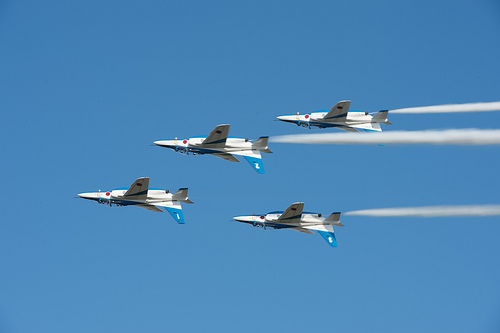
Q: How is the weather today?
A: It is clear.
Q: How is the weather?
A: It is clear.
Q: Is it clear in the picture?
A: Yes, it is clear.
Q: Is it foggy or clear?
A: It is clear.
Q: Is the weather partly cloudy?
A: No, it is clear.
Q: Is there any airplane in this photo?
A: Yes, there is an airplane.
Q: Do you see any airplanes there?
A: Yes, there is an airplane.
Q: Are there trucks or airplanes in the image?
A: Yes, there is an airplane.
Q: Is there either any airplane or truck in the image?
A: Yes, there is an airplane.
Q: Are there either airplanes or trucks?
A: Yes, there is an airplane.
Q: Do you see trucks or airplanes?
A: Yes, there is an airplane.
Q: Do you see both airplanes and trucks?
A: No, there is an airplane but no trucks.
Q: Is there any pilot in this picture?
A: No, there are no pilots.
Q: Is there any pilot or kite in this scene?
A: No, there are no pilots or kites.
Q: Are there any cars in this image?
A: No, there are no cars.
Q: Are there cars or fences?
A: No, there are no cars or fences.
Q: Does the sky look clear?
A: Yes, the sky is clear.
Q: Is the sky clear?
A: Yes, the sky is clear.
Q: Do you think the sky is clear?
A: Yes, the sky is clear.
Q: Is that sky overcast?
A: No, the sky is clear.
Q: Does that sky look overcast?
A: No, the sky is clear.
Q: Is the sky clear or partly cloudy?
A: The sky is clear.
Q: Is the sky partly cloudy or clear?
A: The sky is clear.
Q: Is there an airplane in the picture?
A: Yes, there is an airplane.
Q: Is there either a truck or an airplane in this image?
A: Yes, there is an airplane.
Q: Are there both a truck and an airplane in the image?
A: No, there is an airplane but no trucks.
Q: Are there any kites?
A: No, there are no kites.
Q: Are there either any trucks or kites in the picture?
A: No, there are no kites or trucks.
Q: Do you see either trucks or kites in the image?
A: No, there are no kites or trucks.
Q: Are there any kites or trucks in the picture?
A: No, there are no kites or trucks.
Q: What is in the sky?
A: The plane is in the sky.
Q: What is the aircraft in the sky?
A: The aircraft is an airplane.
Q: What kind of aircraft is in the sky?
A: The aircraft is an airplane.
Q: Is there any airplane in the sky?
A: Yes, there is an airplane in the sky.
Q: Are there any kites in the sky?
A: No, there is an airplane in the sky.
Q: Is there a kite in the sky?
A: No, there is an airplane in the sky.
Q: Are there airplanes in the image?
A: Yes, there is an airplane.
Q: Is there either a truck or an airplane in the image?
A: Yes, there is an airplane.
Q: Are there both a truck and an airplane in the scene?
A: No, there is an airplane but no trucks.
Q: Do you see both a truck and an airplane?
A: No, there is an airplane but no trucks.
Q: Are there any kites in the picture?
A: No, there are no kites.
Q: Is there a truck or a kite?
A: No, there are no kites or trucks.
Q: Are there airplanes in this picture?
A: Yes, there is an airplane.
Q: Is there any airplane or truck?
A: Yes, there is an airplane.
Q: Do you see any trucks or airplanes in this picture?
A: Yes, there is an airplane.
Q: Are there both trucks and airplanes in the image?
A: No, there is an airplane but no trucks.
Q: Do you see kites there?
A: No, there are no kites.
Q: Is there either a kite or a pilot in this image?
A: No, there are no kites or pilots.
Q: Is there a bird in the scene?
A: No, there are no birds.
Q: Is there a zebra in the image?
A: No, there are no zebras.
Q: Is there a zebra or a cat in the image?
A: No, there are no zebras or cats.